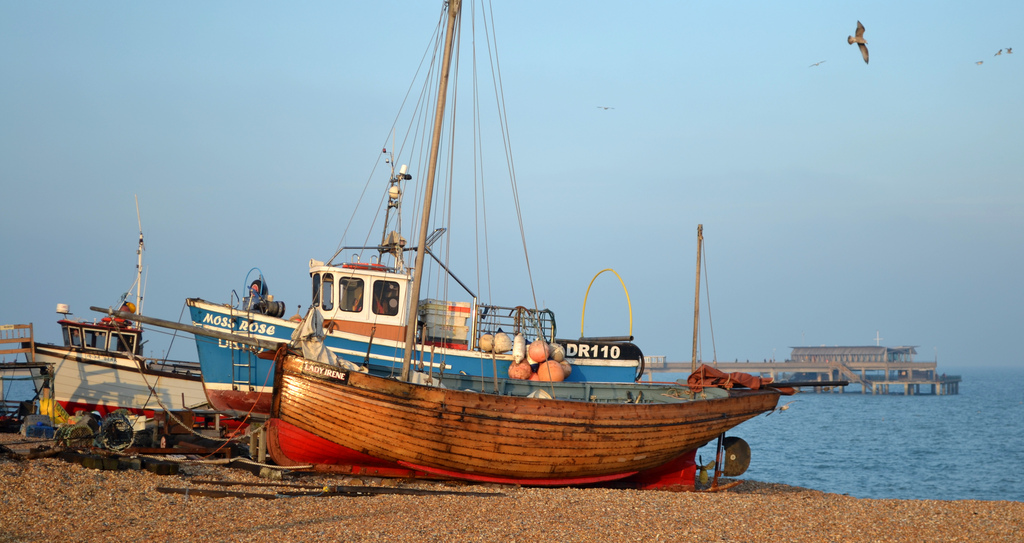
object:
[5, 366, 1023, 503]
water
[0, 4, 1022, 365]
sky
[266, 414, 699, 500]
bottom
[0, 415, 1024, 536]
beach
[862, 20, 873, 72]
wings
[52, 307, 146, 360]
wheel house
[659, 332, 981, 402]
pier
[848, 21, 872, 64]
bird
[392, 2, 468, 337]
mast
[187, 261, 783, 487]
boat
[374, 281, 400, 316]
window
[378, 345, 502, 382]
oar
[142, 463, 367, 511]
plank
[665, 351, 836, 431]
cloth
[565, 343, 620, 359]
letters